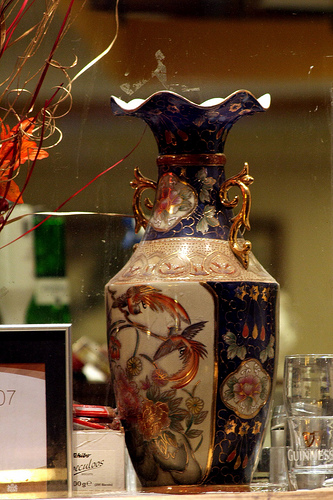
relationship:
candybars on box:
[72, 402, 122, 431] [72, 427, 125, 493]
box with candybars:
[72, 427, 125, 493] [72, 402, 122, 431]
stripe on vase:
[206, 415, 217, 468] [103, 83, 278, 486]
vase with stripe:
[103, 83, 278, 486] [206, 415, 217, 468]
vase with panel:
[96, 83, 279, 486] [197, 274, 278, 483]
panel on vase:
[197, 274, 278, 483] [96, 83, 279, 486]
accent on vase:
[130, 166, 156, 234] [103, 83, 278, 486]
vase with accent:
[103, 83, 278, 486] [130, 166, 156, 234]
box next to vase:
[72, 427, 125, 493] [96, 83, 279, 486]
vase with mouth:
[96, 83, 279, 486] [107, 89, 273, 112]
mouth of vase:
[107, 89, 273, 112] [96, 83, 279, 486]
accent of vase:
[219, 160, 253, 270] [96, 83, 279, 486]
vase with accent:
[96, 83, 279, 486] [219, 160, 253, 270]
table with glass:
[97, 470, 179, 496] [273, 400, 328, 486]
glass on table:
[273, 400, 328, 486] [97, 470, 179, 496]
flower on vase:
[108, 288, 218, 479] [103, 83, 278, 486]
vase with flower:
[103, 83, 278, 486] [108, 288, 218, 479]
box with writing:
[72, 427, 125, 493] [71, 452, 113, 486]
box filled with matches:
[72, 402, 128, 492] [71, 404, 118, 428]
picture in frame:
[2, 323, 72, 498] [2, 323, 74, 498]